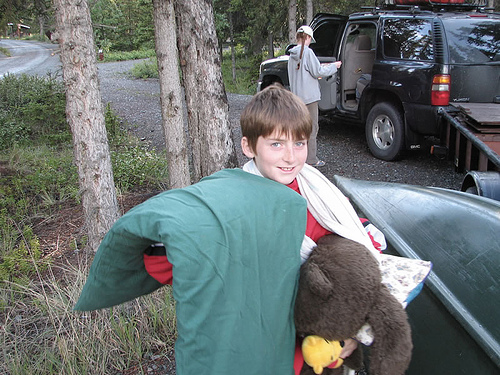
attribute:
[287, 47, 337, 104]
sweatshirt — grey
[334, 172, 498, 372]
kayak — green 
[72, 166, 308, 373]
pillow — green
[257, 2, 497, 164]
van — Black , dirty 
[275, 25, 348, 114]
sweater — grey 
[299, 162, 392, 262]
sheet — white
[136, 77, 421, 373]
boy — little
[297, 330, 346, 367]
pooh bear — stuffed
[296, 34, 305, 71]
pigtails — long 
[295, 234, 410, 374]
stuffed animal — brown , Big 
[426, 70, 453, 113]
light — orange, red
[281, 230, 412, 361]
bear — brown 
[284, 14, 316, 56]
hat — white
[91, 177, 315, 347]
pillow — green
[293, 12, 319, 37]
hat — white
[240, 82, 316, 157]
hair — brown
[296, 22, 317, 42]
hat — white 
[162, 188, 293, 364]
pillow — green